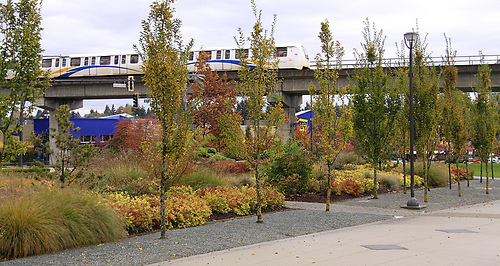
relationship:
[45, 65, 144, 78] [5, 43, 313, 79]
design on train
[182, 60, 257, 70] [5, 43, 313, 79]
design on train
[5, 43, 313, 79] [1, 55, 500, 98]
train on bridge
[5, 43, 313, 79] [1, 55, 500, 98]
train atop bridge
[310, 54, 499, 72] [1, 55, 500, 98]
rail atop te bridge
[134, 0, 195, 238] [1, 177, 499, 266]
tree along sidewalk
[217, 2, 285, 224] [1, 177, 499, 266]
tree along sidewalk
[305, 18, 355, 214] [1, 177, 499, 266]
tree along sidewalk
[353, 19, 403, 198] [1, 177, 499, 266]
tree along sidewalk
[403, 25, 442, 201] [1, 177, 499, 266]
tree along sidewalk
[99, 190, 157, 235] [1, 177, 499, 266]
bush beside sidewalk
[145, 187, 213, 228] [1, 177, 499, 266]
bush beside sidewalk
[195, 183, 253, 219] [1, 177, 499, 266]
bush beside sidewalk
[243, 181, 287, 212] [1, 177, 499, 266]
bush beside sidewalk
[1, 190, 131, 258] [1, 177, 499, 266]
bush beside sidewalk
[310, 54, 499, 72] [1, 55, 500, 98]
rail on bridge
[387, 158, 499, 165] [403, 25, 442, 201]
lot between tree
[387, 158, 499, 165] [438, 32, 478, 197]
lot between tree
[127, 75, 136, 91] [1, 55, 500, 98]
traffic-light hanging besuide bridge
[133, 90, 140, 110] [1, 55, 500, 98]
traffic-light hanging besuide bridge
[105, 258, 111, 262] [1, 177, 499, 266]
leaf on sidewalk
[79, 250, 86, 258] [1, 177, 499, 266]
leaf on sidewalk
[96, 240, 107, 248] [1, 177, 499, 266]
leaf on sidewalk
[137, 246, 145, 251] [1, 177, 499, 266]
leaf on sidewalk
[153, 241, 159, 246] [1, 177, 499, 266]
leaf on sidewalk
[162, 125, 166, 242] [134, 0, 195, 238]
trunk of tree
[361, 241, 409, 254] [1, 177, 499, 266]
manhole on sidewalk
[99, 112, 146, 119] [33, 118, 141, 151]
roof of building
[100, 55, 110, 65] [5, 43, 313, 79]
window on train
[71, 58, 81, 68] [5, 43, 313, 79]
window on train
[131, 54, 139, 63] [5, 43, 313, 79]
window on train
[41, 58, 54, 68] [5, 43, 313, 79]
window on train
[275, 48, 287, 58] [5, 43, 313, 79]
window on train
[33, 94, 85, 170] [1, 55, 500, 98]
support from bridge